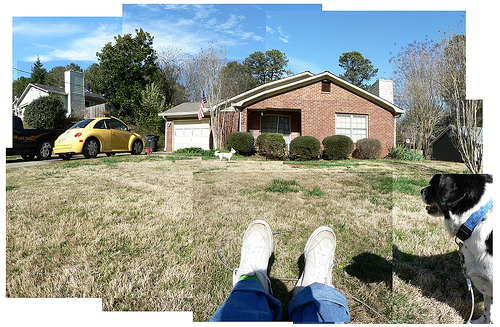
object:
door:
[169, 119, 215, 148]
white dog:
[214, 148, 236, 161]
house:
[158, 70, 406, 159]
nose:
[420, 188, 427, 195]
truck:
[5, 115, 60, 160]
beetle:
[52, 116, 143, 160]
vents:
[322, 79, 332, 92]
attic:
[232, 70, 405, 117]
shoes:
[231, 220, 337, 297]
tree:
[84, 28, 174, 136]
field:
[4, 154, 494, 327]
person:
[208, 220, 351, 327]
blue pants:
[209, 279, 352, 325]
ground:
[338, 51, 380, 91]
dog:
[420, 174, 493, 320]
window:
[335, 112, 370, 143]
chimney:
[369, 79, 394, 103]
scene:
[6, 3, 493, 324]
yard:
[3, 118, 481, 324]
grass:
[3, 190, 265, 297]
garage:
[158, 102, 223, 152]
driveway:
[11, 158, 61, 169]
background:
[10, 16, 466, 158]